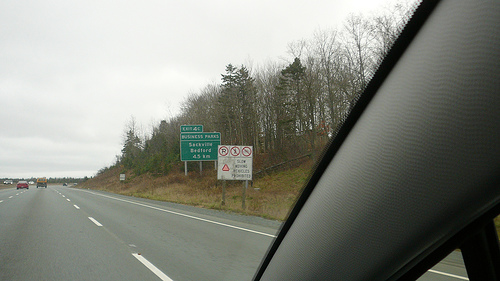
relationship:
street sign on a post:
[215, 145, 255, 179] [240, 177, 247, 209]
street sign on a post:
[215, 145, 255, 179] [220, 176, 225, 210]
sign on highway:
[117, 171, 131, 181] [0, 172, 468, 279]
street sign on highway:
[215, 145, 255, 179] [3, 181, 276, 278]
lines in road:
[56, 187, 171, 278] [15, 192, 220, 259]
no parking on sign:
[215, 142, 231, 158] [205, 135, 312, 215]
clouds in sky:
[14, 8, 308, 169] [0, 0, 420, 177]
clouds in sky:
[0, 0, 422, 177] [0, 0, 420, 177]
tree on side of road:
[270, 55, 325, 170] [2, 187, 464, 279]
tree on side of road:
[211, 56, 247, 176] [2, 187, 464, 279]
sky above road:
[0, 0, 420, 177] [2, 187, 464, 279]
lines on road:
[1, 187, 171, 277] [2, 187, 464, 279]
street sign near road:
[215, 145, 255, 179] [2, 187, 464, 279]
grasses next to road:
[81, 164, 296, 217] [35, 193, 192, 254]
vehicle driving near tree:
[11, 177, 31, 191] [211, 56, 247, 176]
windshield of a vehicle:
[1, 2, 436, 279] [163, 89, 373, 281]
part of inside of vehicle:
[271, 184, 416, 281] [17, 181, 31, 191]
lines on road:
[56, 187, 171, 278] [10, 125, 332, 272]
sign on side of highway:
[178, 120, 223, 162] [0, 172, 468, 279]